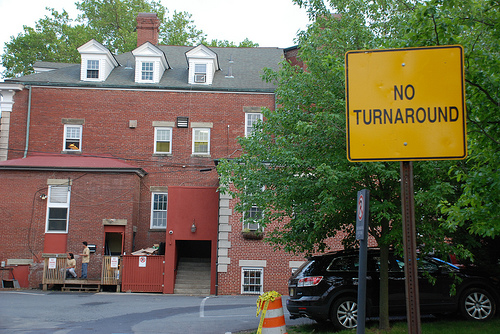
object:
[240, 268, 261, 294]
window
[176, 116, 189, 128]
light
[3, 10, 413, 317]
building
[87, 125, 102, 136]
brick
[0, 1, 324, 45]
sky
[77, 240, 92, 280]
people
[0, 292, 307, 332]
pavement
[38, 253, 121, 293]
deck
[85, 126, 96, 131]
brick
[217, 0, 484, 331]
tree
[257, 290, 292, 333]
cone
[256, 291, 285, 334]
caution tape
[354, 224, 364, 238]
writing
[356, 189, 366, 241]
sign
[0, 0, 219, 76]
trees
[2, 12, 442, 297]
house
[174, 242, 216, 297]
stairway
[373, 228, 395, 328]
trunk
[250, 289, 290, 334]
barrel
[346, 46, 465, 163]
sign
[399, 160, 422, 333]
post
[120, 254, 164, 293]
dumpster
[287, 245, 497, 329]
car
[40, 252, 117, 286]
patio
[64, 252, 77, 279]
person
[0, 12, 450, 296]
building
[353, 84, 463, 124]
"no turnaround"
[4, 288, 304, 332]
lot